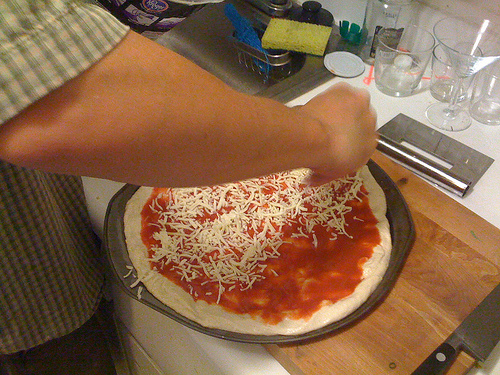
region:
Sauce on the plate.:
[283, 255, 333, 293]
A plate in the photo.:
[376, 217, 411, 303]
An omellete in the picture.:
[125, 216, 355, 331]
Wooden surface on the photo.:
[437, 248, 485, 311]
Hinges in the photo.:
[405, 122, 485, 184]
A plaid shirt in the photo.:
[14, 202, 80, 306]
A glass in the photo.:
[443, 58, 473, 125]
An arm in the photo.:
[128, 65, 379, 180]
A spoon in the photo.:
[467, 18, 493, 52]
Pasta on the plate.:
[207, 209, 274, 267]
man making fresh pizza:
[1, 0, 379, 369]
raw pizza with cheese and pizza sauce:
[123, 135, 394, 337]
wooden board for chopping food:
[216, 131, 496, 373]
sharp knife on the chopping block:
[410, 278, 499, 373]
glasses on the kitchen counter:
[370, 15, 499, 127]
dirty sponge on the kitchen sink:
[258, 17, 333, 56]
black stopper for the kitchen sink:
[286, 1, 337, 31]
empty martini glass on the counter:
[426, 16, 498, 133]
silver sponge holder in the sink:
[227, 21, 292, 78]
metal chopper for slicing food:
[371, 110, 494, 201]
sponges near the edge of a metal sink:
[205, 5, 351, 74]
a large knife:
[408, 280, 497, 374]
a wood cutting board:
[284, 164, 499, 372]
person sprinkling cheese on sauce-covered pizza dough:
[4, 0, 412, 343]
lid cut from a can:
[323, 48, 365, 78]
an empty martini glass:
[426, 11, 498, 129]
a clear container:
[373, 19, 434, 96]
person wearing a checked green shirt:
[1, 0, 130, 353]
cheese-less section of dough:
[278, 246, 388, 330]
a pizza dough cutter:
[377, 110, 494, 202]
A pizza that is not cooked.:
[122, 180, 392, 335]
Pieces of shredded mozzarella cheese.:
[145, 185, 376, 286]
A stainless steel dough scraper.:
[375, 107, 491, 197]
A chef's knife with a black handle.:
[410, 280, 499, 372]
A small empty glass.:
[371, 21, 432, 98]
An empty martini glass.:
[425, 11, 497, 128]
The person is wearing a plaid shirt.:
[0, 0, 130, 351]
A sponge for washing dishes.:
[260, 15, 332, 55]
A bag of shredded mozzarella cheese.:
[100, 0, 211, 40]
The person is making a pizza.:
[0, 0, 375, 340]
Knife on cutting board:
[401, 258, 498, 373]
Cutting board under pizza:
[411, 212, 476, 295]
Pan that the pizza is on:
[393, 197, 417, 253]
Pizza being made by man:
[138, 179, 377, 334]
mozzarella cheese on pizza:
[165, 199, 280, 261]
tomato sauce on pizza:
[286, 245, 348, 295]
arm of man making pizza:
[3, 0, 374, 193]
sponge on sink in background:
[258, 14, 343, 62]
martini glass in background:
[413, 3, 498, 128]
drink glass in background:
[367, 14, 435, 94]